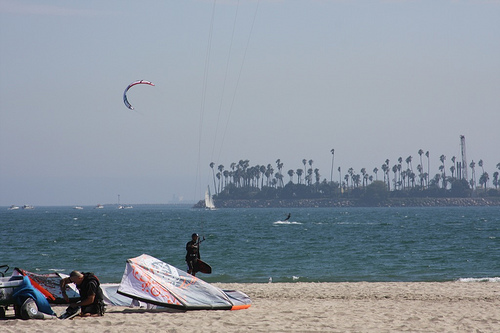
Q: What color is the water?
A: Blue.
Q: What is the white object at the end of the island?
A: A sail.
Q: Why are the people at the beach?
A: Water sports.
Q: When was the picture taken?
A: Daytime.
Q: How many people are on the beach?
A: Two.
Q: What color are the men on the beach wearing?
A: Black.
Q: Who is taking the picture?
A: Photgrapher.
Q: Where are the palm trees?
A: On an island.